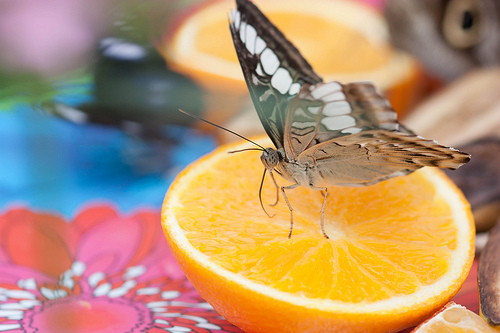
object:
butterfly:
[179, 0, 472, 240]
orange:
[161, 133, 477, 332]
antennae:
[179, 109, 267, 150]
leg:
[281, 183, 300, 239]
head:
[260, 147, 280, 171]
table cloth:
[0, 93, 242, 331]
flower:
[0, 198, 243, 333]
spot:
[259, 48, 280, 76]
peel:
[186, 252, 300, 333]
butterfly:
[30, 33, 205, 148]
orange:
[169, 5, 418, 119]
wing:
[224, 5, 413, 149]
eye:
[268, 156, 276, 164]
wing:
[284, 81, 473, 189]